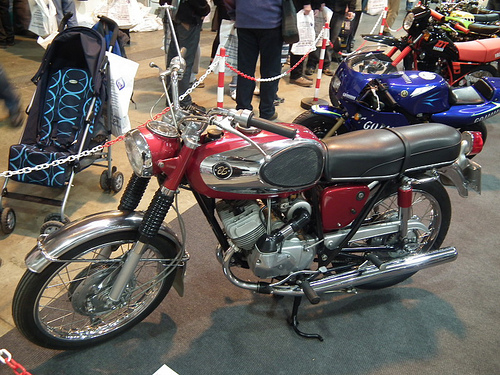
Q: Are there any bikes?
A: Yes, there is a bike.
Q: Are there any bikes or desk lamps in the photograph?
A: Yes, there is a bike.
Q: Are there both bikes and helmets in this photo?
A: No, there is a bike but no helmets.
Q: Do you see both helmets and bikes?
A: No, there is a bike but no helmets.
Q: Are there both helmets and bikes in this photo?
A: No, there is a bike but no helmets.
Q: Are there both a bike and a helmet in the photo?
A: No, there is a bike but no helmets.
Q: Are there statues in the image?
A: No, there are no statues.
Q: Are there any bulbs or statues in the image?
A: No, there are no statues or bulbs.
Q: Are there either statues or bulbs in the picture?
A: No, there are no statues or bulbs.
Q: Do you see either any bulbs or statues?
A: No, there are no statues or bulbs.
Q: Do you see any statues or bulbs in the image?
A: No, there are no statues or bulbs.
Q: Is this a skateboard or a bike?
A: This is a bike.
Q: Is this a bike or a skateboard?
A: This is a bike.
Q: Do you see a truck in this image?
A: No, there are no trucks.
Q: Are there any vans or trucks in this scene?
A: No, there are no trucks or vans.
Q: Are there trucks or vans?
A: No, there are no trucks or vans.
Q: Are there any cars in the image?
A: No, there are no cars.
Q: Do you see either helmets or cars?
A: No, there are no cars or helmets.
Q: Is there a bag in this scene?
A: Yes, there is a bag.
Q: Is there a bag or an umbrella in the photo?
A: Yes, there is a bag.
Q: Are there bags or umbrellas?
A: Yes, there is a bag.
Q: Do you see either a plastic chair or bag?
A: Yes, there is a plastic bag.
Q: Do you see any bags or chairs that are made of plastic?
A: Yes, the bag is made of plastic.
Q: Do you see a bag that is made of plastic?
A: Yes, there is a bag that is made of plastic.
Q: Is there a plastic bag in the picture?
A: Yes, there is a bag that is made of plastic.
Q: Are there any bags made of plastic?
A: Yes, there is a bag that is made of plastic.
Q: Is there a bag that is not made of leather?
A: Yes, there is a bag that is made of plastic.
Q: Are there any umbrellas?
A: No, there are no umbrellas.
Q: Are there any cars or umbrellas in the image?
A: No, there are no umbrellas or cars.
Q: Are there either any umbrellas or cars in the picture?
A: No, there are no umbrellas or cars.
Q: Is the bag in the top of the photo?
A: Yes, the bag is in the top of the image.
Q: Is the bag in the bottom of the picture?
A: No, the bag is in the top of the image.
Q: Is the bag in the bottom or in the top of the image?
A: The bag is in the top of the image.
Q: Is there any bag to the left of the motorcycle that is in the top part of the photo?
A: Yes, there is a bag to the left of the motorbike.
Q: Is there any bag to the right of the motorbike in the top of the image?
A: No, the bag is to the left of the motorcycle.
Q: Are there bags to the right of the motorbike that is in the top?
A: No, the bag is to the left of the motorcycle.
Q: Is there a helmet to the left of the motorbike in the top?
A: No, there is a bag to the left of the motorbike.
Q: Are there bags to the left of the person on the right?
A: Yes, there is a bag to the left of the person.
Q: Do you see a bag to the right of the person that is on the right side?
A: No, the bag is to the left of the person.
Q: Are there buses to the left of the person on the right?
A: No, there is a bag to the left of the person.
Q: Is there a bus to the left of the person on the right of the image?
A: No, there is a bag to the left of the person.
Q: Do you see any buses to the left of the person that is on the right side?
A: No, there is a bag to the left of the person.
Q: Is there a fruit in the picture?
A: No, there are no fruits.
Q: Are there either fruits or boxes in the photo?
A: No, there are no fruits or boxes.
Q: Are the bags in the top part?
A: Yes, the bags are in the top of the image.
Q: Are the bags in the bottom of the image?
A: No, the bags are in the top of the image.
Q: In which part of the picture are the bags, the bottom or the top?
A: The bags are in the top of the image.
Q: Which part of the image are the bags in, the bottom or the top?
A: The bags are in the top of the image.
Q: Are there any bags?
A: Yes, there is a bag.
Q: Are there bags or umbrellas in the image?
A: Yes, there is a bag.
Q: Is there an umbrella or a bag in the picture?
A: Yes, there is a bag.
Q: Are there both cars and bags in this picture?
A: No, there is a bag but no cars.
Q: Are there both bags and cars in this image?
A: No, there is a bag but no cars.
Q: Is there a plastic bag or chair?
A: Yes, there is a plastic bag.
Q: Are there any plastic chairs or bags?
A: Yes, there is a plastic bag.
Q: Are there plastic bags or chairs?
A: Yes, there is a plastic bag.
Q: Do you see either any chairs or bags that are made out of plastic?
A: Yes, the bag is made of plastic.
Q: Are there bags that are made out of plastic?
A: Yes, there is a bag that is made of plastic.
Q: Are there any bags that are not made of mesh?
A: Yes, there is a bag that is made of plastic.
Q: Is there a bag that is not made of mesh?
A: Yes, there is a bag that is made of plastic.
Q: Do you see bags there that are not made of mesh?
A: Yes, there is a bag that is made of plastic.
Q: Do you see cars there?
A: No, there are no cars.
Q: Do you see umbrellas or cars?
A: No, there are no cars or umbrellas.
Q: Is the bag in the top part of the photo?
A: Yes, the bag is in the top of the image.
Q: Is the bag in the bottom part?
A: No, the bag is in the top of the image.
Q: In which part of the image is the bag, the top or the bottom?
A: The bag is in the top of the image.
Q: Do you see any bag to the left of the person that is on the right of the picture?
A: Yes, there is a bag to the left of the person.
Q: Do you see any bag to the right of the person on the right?
A: No, the bag is to the left of the person.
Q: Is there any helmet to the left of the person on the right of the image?
A: No, there is a bag to the left of the person.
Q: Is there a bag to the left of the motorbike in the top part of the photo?
A: Yes, there is a bag to the left of the motorbike.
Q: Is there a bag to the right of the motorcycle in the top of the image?
A: No, the bag is to the left of the motorbike.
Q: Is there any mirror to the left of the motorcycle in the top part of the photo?
A: No, there is a bag to the left of the motorbike.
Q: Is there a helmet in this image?
A: No, there are no helmets.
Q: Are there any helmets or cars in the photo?
A: No, there are no helmets or cars.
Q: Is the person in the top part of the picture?
A: Yes, the person is in the top of the image.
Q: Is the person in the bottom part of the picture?
A: No, the person is in the top of the image.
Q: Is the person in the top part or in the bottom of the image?
A: The person is in the top of the image.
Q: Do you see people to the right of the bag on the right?
A: Yes, there is a person to the right of the bag.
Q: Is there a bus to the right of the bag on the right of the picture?
A: No, there is a person to the right of the bag.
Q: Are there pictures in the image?
A: No, there are no pictures.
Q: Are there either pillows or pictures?
A: No, there are no pictures or pillows.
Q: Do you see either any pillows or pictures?
A: No, there are no pictures or pillows.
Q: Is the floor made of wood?
A: Yes, the floor is made of wood.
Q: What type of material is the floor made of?
A: The floor is made of wood.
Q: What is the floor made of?
A: The floor is made of wood.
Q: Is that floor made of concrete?
A: No, the floor is made of wood.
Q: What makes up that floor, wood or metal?
A: The floor is made of wood.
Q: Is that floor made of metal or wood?
A: The floor is made of wood.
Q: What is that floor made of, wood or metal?
A: The floor is made of wood.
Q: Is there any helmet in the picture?
A: No, there are no helmets.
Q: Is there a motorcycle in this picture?
A: Yes, there is a motorcycle.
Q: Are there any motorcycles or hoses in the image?
A: Yes, there is a motorcycle.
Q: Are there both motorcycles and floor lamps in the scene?
A: No, there is a motorcycle but no floor lamps.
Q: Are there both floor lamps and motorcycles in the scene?
A: No, there is a motorcycle but no floor lamps.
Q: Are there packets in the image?
A: No, there are no packets.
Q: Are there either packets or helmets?
A: No, there are no packets or helmets.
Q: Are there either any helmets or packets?
A: No, there are no packets or helmets.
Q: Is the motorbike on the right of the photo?
A: Yes, the motorbike is on the right of the image.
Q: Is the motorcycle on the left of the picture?
A: No, the motorcycle is on the right of the image.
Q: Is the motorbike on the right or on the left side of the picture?
A: The motorbike is on the right of the image.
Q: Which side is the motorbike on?
A: The motorbike is on the right of the image.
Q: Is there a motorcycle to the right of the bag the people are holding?
A: Yes, there is a motorcycle to the right of the bag.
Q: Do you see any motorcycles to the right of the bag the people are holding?
A: Yes, there is a motorcycle to the right of the bag.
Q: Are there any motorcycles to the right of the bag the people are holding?
A: Yes, there is a motorcycle to the right of the bag.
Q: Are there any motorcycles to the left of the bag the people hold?
A: No, the motorcycle is to the right of the bag.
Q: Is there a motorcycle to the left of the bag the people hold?
A: No, the motorcycle is to the right of the bag.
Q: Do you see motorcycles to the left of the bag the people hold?
A: No, the motorcycle is to the right of the bag.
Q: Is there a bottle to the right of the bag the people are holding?
A: No, there is a motorcycle to the right of the bag.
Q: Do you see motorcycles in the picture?
A: Yes, there is a motorcycle.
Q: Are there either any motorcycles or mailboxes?
A: Yes, there is a motorcycle.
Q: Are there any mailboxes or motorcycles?
A: Yes, there is a motorcycle.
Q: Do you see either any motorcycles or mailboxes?
A: Yes, there is a motorcycle.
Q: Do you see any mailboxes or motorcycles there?
A: Yes, there is a motorcycle.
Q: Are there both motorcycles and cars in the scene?
A: No, there is a motorcycle but no cars.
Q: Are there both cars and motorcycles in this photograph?
A: No, there is a motorcycle but no cars.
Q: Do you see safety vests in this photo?
A: No, there are no safety vests.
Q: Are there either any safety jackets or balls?
A: No, there are no safety jackets or balls.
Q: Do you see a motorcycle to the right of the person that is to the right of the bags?
A: Yes, there is a motorcycle to the right of the person.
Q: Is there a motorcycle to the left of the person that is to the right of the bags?
A: No, the motorcycle is to the right of the person.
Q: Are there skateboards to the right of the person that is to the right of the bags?
A: No, there is a motorcycle to the right of the person.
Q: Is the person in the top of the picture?
A: Yes, the person is in the top of the image.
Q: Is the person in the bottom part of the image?
A: No, the person is in the top of the image.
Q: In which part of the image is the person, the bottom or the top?
A: The person is in the top of the image.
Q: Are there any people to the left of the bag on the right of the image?
A: Yes, there is a person to the left of the bag.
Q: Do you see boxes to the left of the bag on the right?
A: No, there is a person to the left of the bag.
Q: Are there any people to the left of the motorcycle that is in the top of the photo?
A: Yes, there is a person to the left of the motorcycle.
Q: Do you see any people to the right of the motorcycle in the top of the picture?
A: No, the person is to the left of the motorcycle.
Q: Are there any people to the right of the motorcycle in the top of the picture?
A: No, the person is to the left of the motorcycle.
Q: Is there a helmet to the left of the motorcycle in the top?
A: No, there is a person to the left of the motorcycle.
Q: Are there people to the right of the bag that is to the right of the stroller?
A: Yes, there is a person to the right of the bag.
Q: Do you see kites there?
A: No, there are no kites.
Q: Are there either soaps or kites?
A: No, there are no kites or soaps.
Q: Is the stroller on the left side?
A: Yes, the stroller is on the left of the image.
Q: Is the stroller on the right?
A: No, the stroller is on the left of the image.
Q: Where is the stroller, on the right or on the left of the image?
A: The stroller is on the left of the image.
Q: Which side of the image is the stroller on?
A: The stroller is on the left of the image.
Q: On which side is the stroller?
A: The stroller is on the left of the image.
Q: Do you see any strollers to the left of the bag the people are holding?
A: Yes, there is a stroller to the left of the bag.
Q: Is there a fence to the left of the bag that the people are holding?
A: No, there is a stroller to the left of the bag.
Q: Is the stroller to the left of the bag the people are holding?
A: Yes, the stroller is to the left of the bag.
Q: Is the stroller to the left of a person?
A: Yes, the stroller is to the left of a person.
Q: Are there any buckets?
A: No, there are no buckets.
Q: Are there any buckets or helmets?
A: No, there are no buckets or helmets.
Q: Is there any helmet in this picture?
A: No, there are no helmets.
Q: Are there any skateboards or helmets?
A: No, there are no helmets or skateboards.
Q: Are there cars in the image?
A: No, there are no cars.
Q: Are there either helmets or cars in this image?
A: No, there are no cars or helmets.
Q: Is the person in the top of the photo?
A: Yes, the person is in the top of the image.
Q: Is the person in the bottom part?
A: No, the person is in the top of the image.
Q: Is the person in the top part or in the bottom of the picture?
A: The person is in the top of the image.